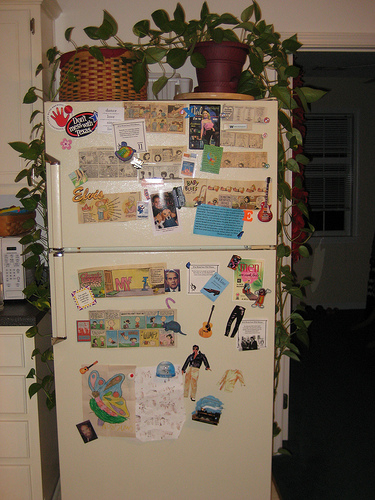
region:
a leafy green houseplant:
[161, 2, 324, 107]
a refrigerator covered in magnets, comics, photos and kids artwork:
[51, 103, 280, 495]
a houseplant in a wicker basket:
[23, 35, 149, 98]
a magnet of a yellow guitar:
[197, 302, 218, 337]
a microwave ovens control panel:
[3, 235, 25, 307]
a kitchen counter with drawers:
[0, 300, 54, 499]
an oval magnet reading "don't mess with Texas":
[66, 111, 99, 136]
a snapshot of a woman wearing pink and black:
[191, 103, 221, 148]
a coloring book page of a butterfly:
[81, 361, 136, 436]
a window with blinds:
[288, 114, 364, 241]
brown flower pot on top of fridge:
[40, 11, 153, 103]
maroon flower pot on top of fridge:
[174, 27, 260, 97]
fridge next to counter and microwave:
[35, 93, 278, 496]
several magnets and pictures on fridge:
[32, 84, 281, 494]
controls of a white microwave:
[1, 235, 28, 300]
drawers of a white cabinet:
[1, 318, 44, 499]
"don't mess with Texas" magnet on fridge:
[62, 109, 98, 136]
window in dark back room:
[294, 106, 364, 240]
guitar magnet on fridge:
[197, 299, 215, 339]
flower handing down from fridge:
[250, 27, 316, 480]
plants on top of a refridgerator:
[31, 2, 311, 122]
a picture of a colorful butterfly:
[72, 354, 138, 432]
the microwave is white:
[0, 226, 31, 304]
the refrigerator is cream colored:
[35, 98, 300, 488]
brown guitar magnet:
[193, 301, 222, 339]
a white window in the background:
[289, 46, 374, 246]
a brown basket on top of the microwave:
[0, 190, 43, 310]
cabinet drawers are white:
[0, 308, 53, 499]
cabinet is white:
[0, 0, 78, 201]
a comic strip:
[81, 303, 185, 351]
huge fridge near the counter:
[42, 100, 276, 494]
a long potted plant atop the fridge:
[23, 9, 302, 451]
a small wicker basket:
[56, 45, 147, 96]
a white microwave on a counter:
[0, 237, 33, 299]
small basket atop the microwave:
[0, 208, 40, 234]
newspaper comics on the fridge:
[79, 262, 180, 349]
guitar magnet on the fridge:
[256, 176, 274, 224]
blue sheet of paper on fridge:
[191, 206, 248, 236]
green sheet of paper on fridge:
[199, 144, 227, 171]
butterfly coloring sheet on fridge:
[80, 362, 137, 437]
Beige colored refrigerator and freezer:
[41, 98, 283, 497]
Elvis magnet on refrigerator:
[177, 342, 211, 402]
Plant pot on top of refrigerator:
[175, 34, 259, 101]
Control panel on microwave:
[2, 237, 25, 297]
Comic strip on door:
[180, 176, 270, 214]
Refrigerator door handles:
[39, 157, 66, 340]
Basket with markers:
[0, 200, 33, 232]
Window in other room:
[294, 111, 354, 235]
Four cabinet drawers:
[0, 325, 31, 491]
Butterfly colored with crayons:
[81, 366, 135, 429]